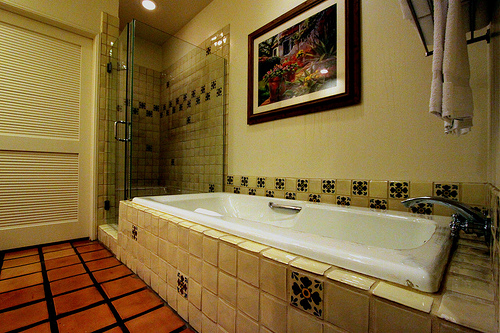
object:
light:
[139, 0, 160, 13]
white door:
[0, 26, 115, 257]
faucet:
[400, 195, 490, 243]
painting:
[243, 0, 361, 128]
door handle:
[113, 117, 131, 143]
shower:
[102, 11, 224, 250]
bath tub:
[132, 192, 460, 302]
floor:
[0, 240, 150, 327]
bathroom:
[1, 4, 494, 331]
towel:
[398, 0, 476, 137]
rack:
[407, 0, 495, 59]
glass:
[106, 19, 226, 232]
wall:
[168, 2, 495, 220]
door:
[105, 20, 231, 229]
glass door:
[99, 22, 138, 233]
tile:
[175, 272, 190, 299]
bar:
[269, 201, 302, 211]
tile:
[280, 266, 328, 323]